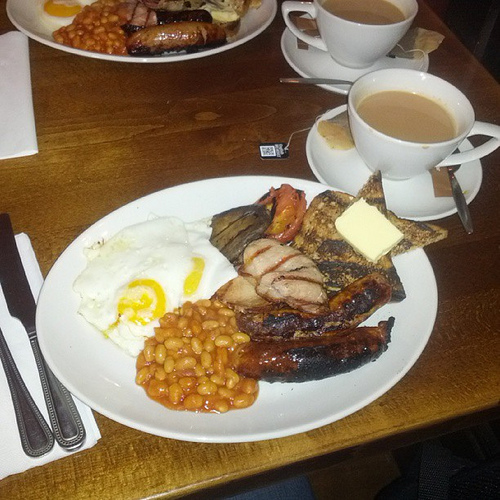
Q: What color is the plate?
A: White.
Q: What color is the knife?
A: Silver.